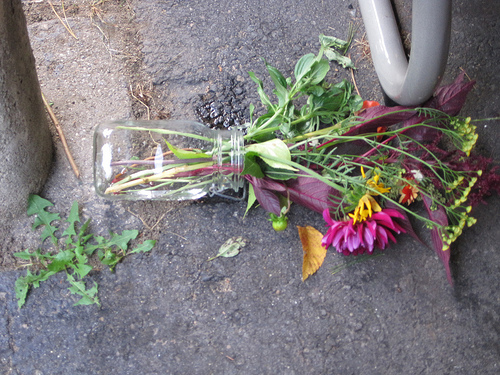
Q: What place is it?
A: It is a pavement.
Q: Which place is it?
A: It is a pavement.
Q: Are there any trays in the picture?
A: No, there are no trays.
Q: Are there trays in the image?
A: No, there are no trays.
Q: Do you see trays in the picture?
A: No, there are no trays.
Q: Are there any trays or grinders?
A: No, there are no trays or grinders.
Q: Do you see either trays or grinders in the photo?
A: No, there are no trays or grinders.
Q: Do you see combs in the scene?
A: No, there are no combs.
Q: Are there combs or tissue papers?
A: No, there are no combs or tissue papers.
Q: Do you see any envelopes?
A: No, there are no envelopes.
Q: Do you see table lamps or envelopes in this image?
A: No, there are no envelopes or table lamps.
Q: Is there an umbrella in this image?
A: No, there are no umbrellas.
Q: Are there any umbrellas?
A: No, there are no umbrellas.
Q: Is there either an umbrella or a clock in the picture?
A: No, there are no umbrellas or clocks.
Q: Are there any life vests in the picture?
A: No, there are no life vests.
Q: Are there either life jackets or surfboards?
A: No, there are no life jackets or surfboards.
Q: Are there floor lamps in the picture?
A: No, there are no floor lamps.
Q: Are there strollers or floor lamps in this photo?
A: No, there are no floor lamps or strollers.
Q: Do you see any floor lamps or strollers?
A: No, there are no floor lamps or strollers.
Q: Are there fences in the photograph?
A: No, there are no fences.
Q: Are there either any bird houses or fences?
A: No, there are no fences or bird houses.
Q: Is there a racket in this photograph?
A: No, there are no rackets.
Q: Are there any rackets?
A: No, there are no rackets.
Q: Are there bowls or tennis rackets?
A: No, there are no tennis rackets or bowls.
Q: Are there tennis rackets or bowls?
A: No, there are no tennis rackets or bowls.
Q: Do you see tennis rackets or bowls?
A: No, there are no tennis rackets or bowls.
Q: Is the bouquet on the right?
A: Yes, the bouquet is on the right of the image.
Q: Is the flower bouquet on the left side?
A: No, the flower bouquet is on the right of the image.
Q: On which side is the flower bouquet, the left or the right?
A: The flower bouquet is on the right of the image.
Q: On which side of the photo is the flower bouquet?
A: The flower bouquet is on the right of the image.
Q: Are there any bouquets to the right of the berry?
A: Yes, there is a bouquet to the right of the berry.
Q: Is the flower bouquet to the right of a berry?
A: Yes, the flower bouquet is to the right of a berry.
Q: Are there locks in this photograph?
A: No, there are no locks.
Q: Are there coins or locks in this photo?
A: No, there are no locks or coins.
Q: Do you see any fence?
A: No, there are no fences.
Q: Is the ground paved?
A: Yes, the ground is paved.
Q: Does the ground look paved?
A: Yes, the ground is paved.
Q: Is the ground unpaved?
A: No, the ground is paved.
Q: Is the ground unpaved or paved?
A: The ground is paved.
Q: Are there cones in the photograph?
A: No, there are no cones.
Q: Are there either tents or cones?
A: No, there are no cones or tents.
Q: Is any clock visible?
A: No, there are no clocks.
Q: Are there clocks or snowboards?
A: No, there are no clocks or snowboards.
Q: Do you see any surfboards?
A: No, there are no surfboards.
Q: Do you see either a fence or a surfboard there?
A: No, there are no surfboards or fences.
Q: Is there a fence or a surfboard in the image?
A: No, there are no surfboards or fences.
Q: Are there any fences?
A: No, there are no fences.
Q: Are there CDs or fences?
A: No, there are no fences or cds.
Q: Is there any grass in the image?
A: Yes, there is grass.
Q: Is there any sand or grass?
A: Yes, there is grass.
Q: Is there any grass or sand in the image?
A: Yes, there is grass.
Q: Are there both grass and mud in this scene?
A: No, there is grass but no mud.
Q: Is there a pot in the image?
A: No, there are no pots.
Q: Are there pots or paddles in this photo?
A: No, there are no pots or paddles.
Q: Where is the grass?
A: The grass is on the ground.